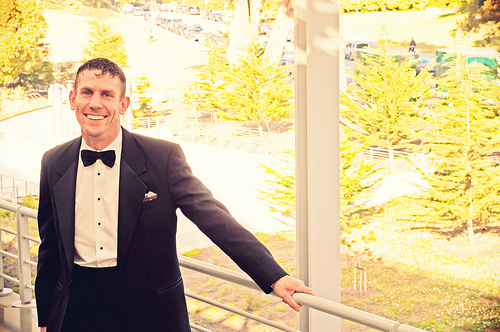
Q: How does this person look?
A: Happy.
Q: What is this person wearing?
A: Tuxedo.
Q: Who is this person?
A: Man.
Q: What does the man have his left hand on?
A: Rail.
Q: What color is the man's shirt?
A: White.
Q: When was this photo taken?
A: Daytime.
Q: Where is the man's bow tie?
A: On collar of shirt.